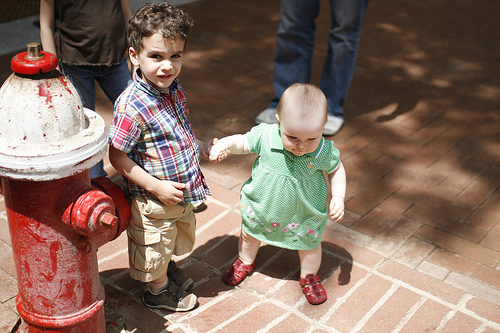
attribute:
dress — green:
[245, 127, 322, 242]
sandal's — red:
[219, 257, 328, 304]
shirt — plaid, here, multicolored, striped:
[107, 74, 213, 207]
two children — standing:
[105, 0, 348, 314]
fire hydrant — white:
[0, 39, 136, 332]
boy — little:
[104, 2, 212, 317]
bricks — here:
[346, 183, 499, 324]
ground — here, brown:
[19, 27, 491, 325]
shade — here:
[206, 6, 500, 120]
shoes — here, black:
[133, 261, 203, 314]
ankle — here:
[139, 282, 166, 312]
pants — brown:
[123, 195, 204, 276]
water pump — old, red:
[14, 32, 125, 328]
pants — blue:
[265, 0, 376, 109]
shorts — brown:
[124, 187, 199, 281]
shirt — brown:
[52, 0, 134, 68]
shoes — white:
[259, 108, 340, 136]